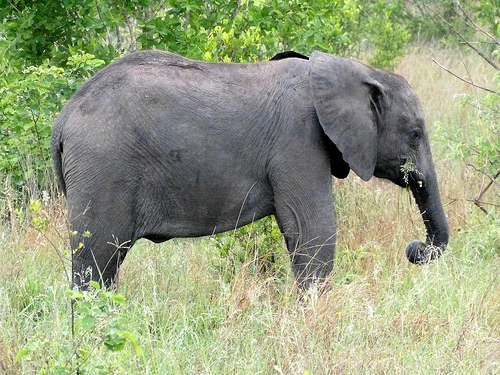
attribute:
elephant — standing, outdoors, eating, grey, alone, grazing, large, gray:
[49, 44, 452, 302]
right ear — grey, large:
[305, 45, 383, 181]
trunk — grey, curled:
[404, 169, 450, 275]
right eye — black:
[409, 123, 424, 142]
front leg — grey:
[263, 132, 341, 292]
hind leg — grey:
[65, 163, 138, 292]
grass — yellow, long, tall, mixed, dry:
[2, 44, 499, 371]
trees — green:
[2, 2, 421, 210]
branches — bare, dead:
[416, 3, 499, 220]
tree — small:
[26, 203, 129, 372]